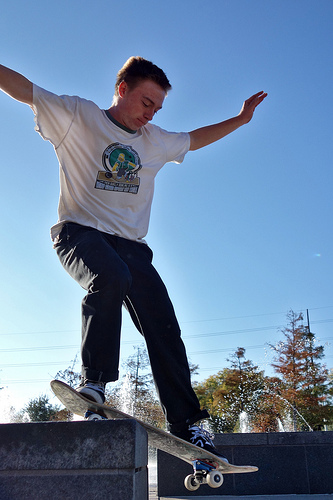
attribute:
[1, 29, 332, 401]
sky — blue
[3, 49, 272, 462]
boy — skating